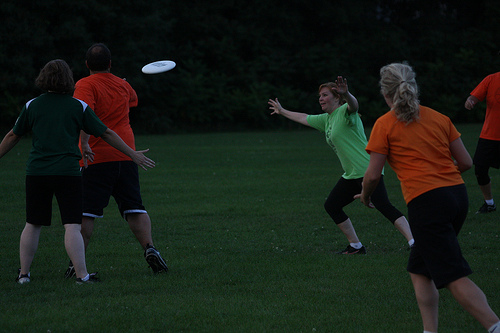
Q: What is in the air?
A: Frisbee.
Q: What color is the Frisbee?
A: White.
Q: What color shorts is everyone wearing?
A: Black.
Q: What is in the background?
A: Trees.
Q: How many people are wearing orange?
A: Three.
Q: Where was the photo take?
A: At a frisbee match.